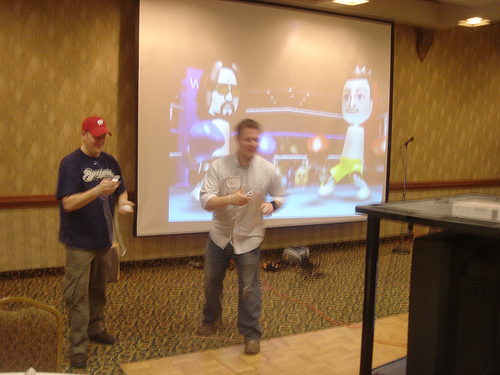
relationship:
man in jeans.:
[198, 120, 288, 356] [202, 233, 264, 328]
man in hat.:
[57, 115, 138, 370] [80, 116, 114, 137]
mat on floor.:
[131, 327, 399, 373] [32, 249, 344, 335]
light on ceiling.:
[461, 16, 490, 32] [370, 1, 498, 29]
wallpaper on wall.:
[440, 32, 500, 179] [1, 4, 496, 185]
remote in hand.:
[113, 174, 121, 181] [97, 180, 124, 195]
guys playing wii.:
[55, 113, 286, 369] [450, 198, 499, 220]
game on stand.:
[450, 198, 499, 220] [356, 196, 498, 375]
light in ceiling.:
[461, 16, 490, 32] [370, 1, 498, 29]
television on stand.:
[406, 230, 499, 374] [356, 196, 498, 375]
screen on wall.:
[136, 2, 400, 231] [1, 4, 496, 185]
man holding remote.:
[198, 120, 288, 356] [243, 190, 257, 197]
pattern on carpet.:
[120, 295, 137, 316] [5, 251, 326, 325]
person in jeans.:
[198, 120, 288, 356] [202, 233, 264, 328]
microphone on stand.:
[403, 135, 415, 151] [398, 145, 408, 238]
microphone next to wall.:
[403, 135, 415, 151] [1, 4, 496, 185]